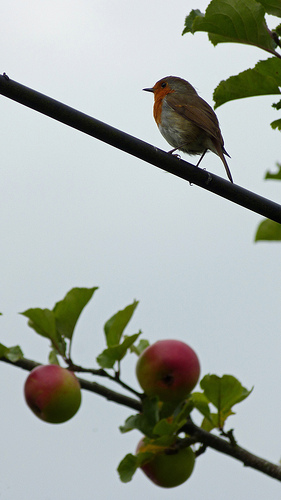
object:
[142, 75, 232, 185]
bird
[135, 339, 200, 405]
apples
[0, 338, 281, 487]
tree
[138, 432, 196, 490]
apples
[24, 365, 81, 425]
apples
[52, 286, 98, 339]
leaves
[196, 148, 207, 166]
legs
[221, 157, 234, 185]
tail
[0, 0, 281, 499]
sky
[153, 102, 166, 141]
bird's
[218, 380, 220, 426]
vein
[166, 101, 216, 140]
long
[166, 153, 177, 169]
claw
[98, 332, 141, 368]
green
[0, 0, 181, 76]
powder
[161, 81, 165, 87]
bird's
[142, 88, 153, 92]
beak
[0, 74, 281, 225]
branch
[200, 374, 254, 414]
leaf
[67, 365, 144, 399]
twigs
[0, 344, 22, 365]
small leaf